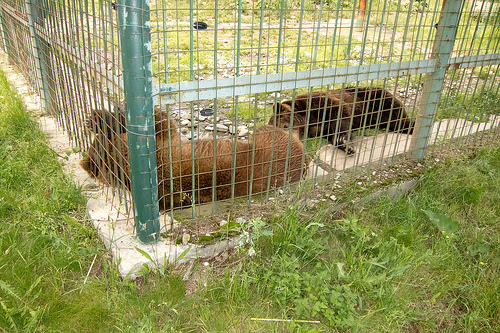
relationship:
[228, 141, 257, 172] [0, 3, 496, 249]
square on cage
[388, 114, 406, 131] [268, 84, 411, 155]
paw on bear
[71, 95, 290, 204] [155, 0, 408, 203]
dog in a cage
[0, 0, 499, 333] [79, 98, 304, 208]
weed by bear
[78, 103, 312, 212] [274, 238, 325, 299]
bear by weed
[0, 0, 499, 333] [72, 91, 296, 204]
weed by bear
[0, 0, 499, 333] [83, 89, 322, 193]
weed by bear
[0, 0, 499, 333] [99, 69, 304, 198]
weed by bear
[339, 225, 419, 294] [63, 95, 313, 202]
weed by bear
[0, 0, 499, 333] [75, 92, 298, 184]
weed by bear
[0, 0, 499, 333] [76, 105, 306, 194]
weed by bear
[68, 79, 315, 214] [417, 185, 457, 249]
bear by weed